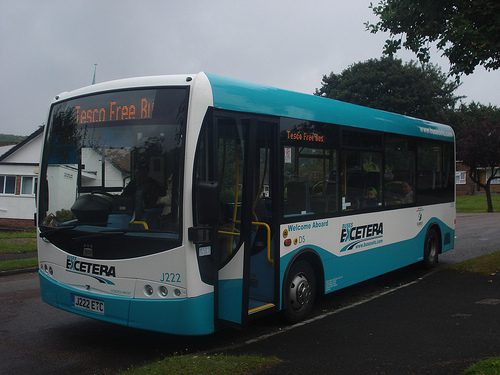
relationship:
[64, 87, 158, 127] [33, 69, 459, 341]
jesco free bus on front of bus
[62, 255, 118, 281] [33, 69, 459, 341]
excetera on front of bus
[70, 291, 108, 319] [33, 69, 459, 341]
plate j222 etc on front of bus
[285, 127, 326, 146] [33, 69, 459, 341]
tesco free bus on side of bus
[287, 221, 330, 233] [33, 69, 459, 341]
welcome aboard on side of bus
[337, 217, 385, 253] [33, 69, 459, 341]
excetera on side of bus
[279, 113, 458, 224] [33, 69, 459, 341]
passenger windows are on side of bus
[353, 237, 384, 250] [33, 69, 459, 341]
website on side of bus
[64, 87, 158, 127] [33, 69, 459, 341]
marquee display on front of bus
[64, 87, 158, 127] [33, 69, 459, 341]
marquee display on side of bus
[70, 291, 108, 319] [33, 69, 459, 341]
license plate on front of bus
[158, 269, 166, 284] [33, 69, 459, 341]
letter j on front of bus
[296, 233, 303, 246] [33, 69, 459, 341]
letter d on side of bus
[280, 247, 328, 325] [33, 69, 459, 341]
tire on side of bus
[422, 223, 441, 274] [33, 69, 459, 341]
tire on side of bus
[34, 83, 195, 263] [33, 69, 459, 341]
windshield window on front of bus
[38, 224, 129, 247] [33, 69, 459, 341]
windshield wipers are on front of bus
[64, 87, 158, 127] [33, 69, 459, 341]
tesco free bus on top of bus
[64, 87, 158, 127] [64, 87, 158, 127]
tesco free bus reads tesco free bus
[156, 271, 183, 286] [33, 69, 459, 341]
j222 on front of bus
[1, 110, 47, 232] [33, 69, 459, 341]
house to left of bus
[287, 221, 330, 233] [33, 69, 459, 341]
welcome aboard written on side of bus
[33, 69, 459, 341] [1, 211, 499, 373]
bus traveling on street